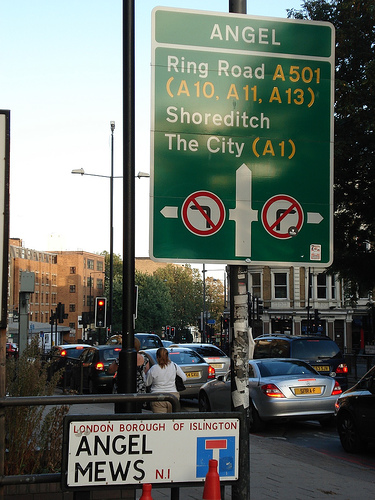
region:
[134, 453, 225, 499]
Two red traffic cones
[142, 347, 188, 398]
Woman carrying a bag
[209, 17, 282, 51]
The word "ANGEL" on a sign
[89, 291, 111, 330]
Traffic light is lit up red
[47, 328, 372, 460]
Many cars on the road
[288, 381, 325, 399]
A yellow license plate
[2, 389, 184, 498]
A black metal railing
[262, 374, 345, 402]
Two red rear lights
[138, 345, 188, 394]
Woman is wearing a white shirt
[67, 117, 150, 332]
A tall street lamp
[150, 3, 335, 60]
Green and white Angel sign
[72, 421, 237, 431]
London Borough of Islington in red text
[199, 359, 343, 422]
Silver car driving left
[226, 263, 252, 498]
Metal pole holding up sign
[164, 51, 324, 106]
Ring Road A501 (A10, A11, A13) label on sign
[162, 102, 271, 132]
Shoreditch label on sign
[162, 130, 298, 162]
The City (A1) label on sign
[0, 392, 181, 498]
Metal fence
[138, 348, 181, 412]
Person wearing a white shirt and khakis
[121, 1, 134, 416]
Metal pole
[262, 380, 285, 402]
the tail light of a car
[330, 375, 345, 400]
the tail light of a car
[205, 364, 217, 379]
the tail light of a car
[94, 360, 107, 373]
the tail light of a car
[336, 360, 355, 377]
the tail light of a car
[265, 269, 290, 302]
the window of a building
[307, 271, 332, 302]
the window of a building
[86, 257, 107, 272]
the windows of a building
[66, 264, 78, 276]
the window of a building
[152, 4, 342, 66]
the word ANGEL on a road sign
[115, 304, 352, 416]
A very busy city street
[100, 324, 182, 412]
Two women walking on a city streeet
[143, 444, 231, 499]
Two orange traffic cones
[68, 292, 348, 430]
Cars stopped at an intersection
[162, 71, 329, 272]
A street sign on a busy street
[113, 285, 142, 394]
A pole for a strret light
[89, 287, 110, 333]
A traffic signal that is lit up red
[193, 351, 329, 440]
A small silver car with its brakes on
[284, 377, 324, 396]
A yellow license plate on a car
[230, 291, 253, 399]
This pole has lots of gray tape on it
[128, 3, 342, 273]
sign on a pole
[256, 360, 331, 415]
car on a street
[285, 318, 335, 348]
car on a street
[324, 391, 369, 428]
car on a street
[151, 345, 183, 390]
girl wearing a white shirt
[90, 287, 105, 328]
traffic light on street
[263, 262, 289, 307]
window on a building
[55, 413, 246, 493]
sign on a street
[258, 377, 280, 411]
light on a car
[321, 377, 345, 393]
light on a car